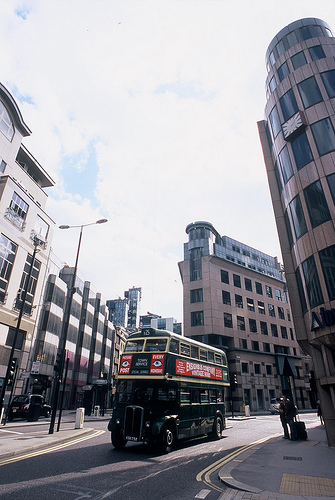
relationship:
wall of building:
[275, 144, 305, 281] [220, 22, 309, 424]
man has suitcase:
[276, 392, 298, 438] [288, 412, 308, 441]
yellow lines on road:
[195, 438, 283, 488] [0, 408, 332, 498]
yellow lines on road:
[1, 426, 105, 467] [0, 408, 332, 498]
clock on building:
[280, 110, 307, 141] [255, 17, 333, 447]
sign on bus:
[173, 355, 225, 380] [126, 313, 274, 471]